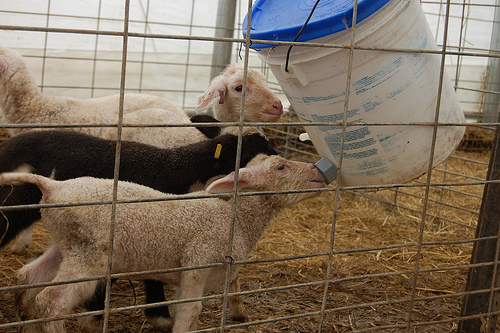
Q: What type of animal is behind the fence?
A: Sheep.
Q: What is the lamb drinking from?
A: Bucket.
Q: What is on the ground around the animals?
A: Hay.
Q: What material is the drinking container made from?
A: Plastic.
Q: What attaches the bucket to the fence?
A: Handle.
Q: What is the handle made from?
A: Metal.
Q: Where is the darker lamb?
A: Middle.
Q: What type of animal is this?
A: Lambs.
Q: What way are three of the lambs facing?
A: Right.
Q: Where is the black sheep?
A: In the middle.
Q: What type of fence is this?
A: Metal.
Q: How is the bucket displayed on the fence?
A: Tilted.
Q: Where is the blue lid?
A: On top of bucket.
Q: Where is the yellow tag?
A: On black lamb's ear.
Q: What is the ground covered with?
A: Hay.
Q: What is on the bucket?
A: Blue writing.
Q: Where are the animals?
A: In a cage.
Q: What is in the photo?
A: Some animals.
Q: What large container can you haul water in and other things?
A: Bucket.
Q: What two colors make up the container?
A: Blue and white.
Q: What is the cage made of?
A: Metal.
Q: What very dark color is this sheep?
A: Black.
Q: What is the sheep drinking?
A: Water.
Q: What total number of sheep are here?
A: Four.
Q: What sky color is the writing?
A: Blue.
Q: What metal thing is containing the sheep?
A: Cage.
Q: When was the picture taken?
A: While one of the lambs was feeding.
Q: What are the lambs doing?
A: Feeding.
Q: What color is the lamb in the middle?
A: Black.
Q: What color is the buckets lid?
A: Blue.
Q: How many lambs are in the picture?
A: Four.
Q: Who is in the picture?
A: There are no people in the picture.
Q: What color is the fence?
A: Silver.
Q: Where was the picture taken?
A: In a zoo.